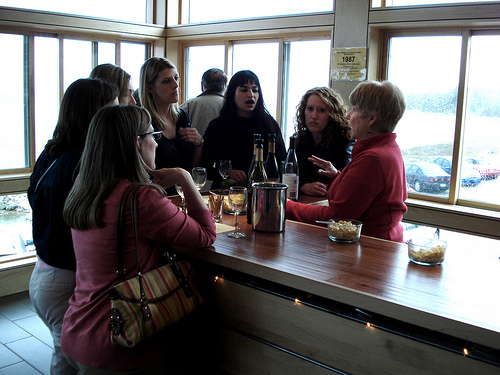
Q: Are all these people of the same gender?
A: Yes, all the people are female.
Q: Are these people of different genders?
A: No, all the people are female.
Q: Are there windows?
A: Yes, there is a window.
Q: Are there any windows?
A: Yes, there is a window.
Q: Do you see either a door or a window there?
A: Yes, there is a window.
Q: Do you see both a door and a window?
A: No, there is a window but no doors.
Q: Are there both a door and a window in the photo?
A: No, there is a window but no doors.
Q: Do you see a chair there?
A: No, there are no chairs.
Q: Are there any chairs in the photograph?
A: No, there are no chairs.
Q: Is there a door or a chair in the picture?
A: No, there are no chairs or doors.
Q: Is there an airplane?
A: No, there are no airplanes.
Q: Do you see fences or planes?
A: No, there are no planes or fences.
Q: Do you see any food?
A: Yes, there is food.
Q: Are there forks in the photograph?
A: No, there are no forks.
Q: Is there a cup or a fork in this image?
A: No, there are no forks or cups.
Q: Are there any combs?
A: No, there are no combs.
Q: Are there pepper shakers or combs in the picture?
A: No, there are no combs or pepper shakers.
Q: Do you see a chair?
A: No, there are no chairs.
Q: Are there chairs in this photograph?
A: No, there are no chairs.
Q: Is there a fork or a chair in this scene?
A: No, there are no chairs or forks.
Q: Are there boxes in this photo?
A: No, there are no boxes.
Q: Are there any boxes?
A: No, there are no boxes.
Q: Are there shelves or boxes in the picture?
A: No, there are no boxes or shelves.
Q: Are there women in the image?
A: Yes, there is a woman.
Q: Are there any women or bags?
A: Yes, there is a woman.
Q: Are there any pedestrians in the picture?
A: No, there are no pedestrians.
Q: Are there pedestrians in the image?
A: No, there are no pedestrians.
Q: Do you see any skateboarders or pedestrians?
A: No, there are no pedestrians or skateboarders.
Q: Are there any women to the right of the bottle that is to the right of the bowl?
A: Yes, there is a woman to the right of the bottle.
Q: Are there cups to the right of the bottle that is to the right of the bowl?
A: No, there is a woman to the right of the bottle.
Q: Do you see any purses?
A: Yes, there is a purse.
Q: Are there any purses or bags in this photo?
A: Yes, there is a purse.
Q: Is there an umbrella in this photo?
A: No, there are no umbrellas.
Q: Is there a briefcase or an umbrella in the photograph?
A: No, there are no umbrellas or briefcases.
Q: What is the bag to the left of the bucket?
A: The bag is a purse.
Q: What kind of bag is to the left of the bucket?
A: The bag is a purse.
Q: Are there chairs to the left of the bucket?
A: No, there is a purse to the left of the bucket.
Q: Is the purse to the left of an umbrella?
A: No, the purse is to the left of the bucket.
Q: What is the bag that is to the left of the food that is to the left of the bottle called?
A: The bag is a purse.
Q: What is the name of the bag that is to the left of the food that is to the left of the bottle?
A: The bag is a purse.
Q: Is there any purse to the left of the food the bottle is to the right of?
A: Yes, there is a purse to the left of the food.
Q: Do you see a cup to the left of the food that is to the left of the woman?
A: No, there is a purse to the left of the food.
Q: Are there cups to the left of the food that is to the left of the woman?
A: No, there is a purse to the left of the food.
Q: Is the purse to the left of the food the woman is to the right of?
A: Yes, the purse is to the left of the food.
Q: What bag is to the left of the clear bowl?
A: The bag is a purse.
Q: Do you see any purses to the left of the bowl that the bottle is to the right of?
A: Yes, there is a purse to the left of the bowl.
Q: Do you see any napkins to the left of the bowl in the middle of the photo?
A: No, there is a purse to the left of the bowl.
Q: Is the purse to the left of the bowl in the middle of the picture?
A: Yes, the purse is to the left of the bowl.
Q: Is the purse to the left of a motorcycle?
A: No, the purse is to the left of the bowl.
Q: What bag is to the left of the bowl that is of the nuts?
A: The bag is a purse.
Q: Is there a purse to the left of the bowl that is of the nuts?
A: Yes, there is a purse to the left of the bowl.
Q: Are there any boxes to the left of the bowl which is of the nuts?
A: No, there is a purse to the left of the bowl.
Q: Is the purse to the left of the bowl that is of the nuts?
A: Yes, the purse is to the left of the bowl.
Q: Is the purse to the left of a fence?
A: No, the purse is to the left of the bowl.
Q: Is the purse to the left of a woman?
A: No, the purse is to the right of a woman.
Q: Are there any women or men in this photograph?
A: Yes, there is a woman.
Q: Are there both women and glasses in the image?
A: Yes, there are both a woman and glasses.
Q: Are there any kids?
A: No, there are no kids.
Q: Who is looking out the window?
A: The woman is looking out the window.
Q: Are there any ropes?
A: No, there are no ropes.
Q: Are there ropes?
A: No, there are no ropes.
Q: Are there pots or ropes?
A: No, there are no ropes or pots.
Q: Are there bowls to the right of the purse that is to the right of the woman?
A: Yes, there is a bowl to the right of the purse.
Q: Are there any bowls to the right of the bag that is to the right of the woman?
A: Yes, there is a bowl to the right of the purse.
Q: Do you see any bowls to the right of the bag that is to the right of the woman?
A: Yes, there is a bowl to the right of the purse.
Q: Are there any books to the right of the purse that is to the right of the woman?
A: No, there is a bowl to the right of the purse.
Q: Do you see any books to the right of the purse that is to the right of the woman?
A: No, there is a bowl to the right of the purse.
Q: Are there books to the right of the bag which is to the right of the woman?
A: No, there is a bowl to the right of the purse.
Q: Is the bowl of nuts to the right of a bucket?
A: Yes, the bowl is to the right of a bucket.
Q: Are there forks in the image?
A: No, there are no forks.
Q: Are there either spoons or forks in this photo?
A: No, there are no forks or spoons.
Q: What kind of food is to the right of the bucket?
A: The food is nuts.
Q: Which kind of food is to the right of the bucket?
A: The food is nuts.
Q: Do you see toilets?
A: No, there are no toilets.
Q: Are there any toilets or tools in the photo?
A: No, there are no toilets or tools.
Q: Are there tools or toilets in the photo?
A: No, there are no toilets or tools.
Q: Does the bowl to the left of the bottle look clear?
A: Yes, the bowl is clear.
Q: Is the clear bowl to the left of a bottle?
A: Yes, the bowl is to the left of a bottle.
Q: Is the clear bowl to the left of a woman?
A: Yes, the bowl is to the left of a woman.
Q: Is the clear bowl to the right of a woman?
A: No, the bowl is to the left of a woman.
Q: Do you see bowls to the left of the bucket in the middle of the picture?
A: Yes, there is a bowl to the left of the bucket.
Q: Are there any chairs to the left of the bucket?
A: No, there is a bowl to the left of the bucket.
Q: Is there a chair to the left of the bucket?
A: No, there is a bowl to the left of the bucket.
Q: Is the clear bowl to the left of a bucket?
A: Yes, the bowl is to the left of a bucket.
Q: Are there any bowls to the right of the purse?
A: Yes, there is a bowl to the right of the purse.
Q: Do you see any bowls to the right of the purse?
A: Yes, there is a bowl to the right of the purse.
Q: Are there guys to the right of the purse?
A: No, there is a bowl to the right of the purse.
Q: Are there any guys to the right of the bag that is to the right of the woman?
A: No, there is a bowl to the right of the purse.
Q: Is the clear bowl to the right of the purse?
A: Yes, the bowl is to the right of the purse.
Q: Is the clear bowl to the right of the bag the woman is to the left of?
A: Yes, the bowl is to the right of the purse.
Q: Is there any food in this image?
A: Yes, there is food.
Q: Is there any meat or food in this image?
A: Yes, there is food.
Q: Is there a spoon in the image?
A: No, there are no spoons.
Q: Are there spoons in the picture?
A: No, there are no spoons.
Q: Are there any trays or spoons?
A: No, there are no spoons or trays.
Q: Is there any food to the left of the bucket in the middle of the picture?
A: Yes, there is food to the left of the bucket.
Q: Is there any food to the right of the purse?
A: Yes, there is food to the right of the purse.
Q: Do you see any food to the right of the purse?
A: Yes, there is food to the right of the purse.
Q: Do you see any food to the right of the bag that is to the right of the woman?
A: Yes, there is food to the right of the purse.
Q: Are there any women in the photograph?
A: Yes, there is a woman.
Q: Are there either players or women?
A: Yes, there is a woman.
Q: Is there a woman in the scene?
A: Yes, there is a woman.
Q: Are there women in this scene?
A: Yes, there is a woman.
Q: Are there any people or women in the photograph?
A: Yes, there is a woman.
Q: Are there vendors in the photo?
A: No, there are no vendors.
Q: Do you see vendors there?
A: No, there are no vendors.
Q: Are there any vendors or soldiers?
A: No, there are no vendors or soldiers.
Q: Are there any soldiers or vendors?
A: No, there are no vendors or soldiers.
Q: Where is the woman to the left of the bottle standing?
A: The woman is standing at the table.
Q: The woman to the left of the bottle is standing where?
A: The woman is standing at the table.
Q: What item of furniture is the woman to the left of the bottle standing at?
A: The woman is standing at the table.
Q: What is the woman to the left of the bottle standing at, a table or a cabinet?
A: The woman is standing at a table.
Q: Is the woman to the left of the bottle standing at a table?
A: Yes, the woman is standing at a table.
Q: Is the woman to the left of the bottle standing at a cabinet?
A: No, the woman is standing at a table.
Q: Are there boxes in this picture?
A: No, there are no boxes.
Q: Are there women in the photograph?
A: Yes, there is a woman.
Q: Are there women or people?
A: Yes, there is a woman.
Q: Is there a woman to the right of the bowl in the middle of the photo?
A: Yes, there is a woman to the right of the bowl.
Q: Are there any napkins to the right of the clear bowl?
A: No, there is a woman to the right of the bowl.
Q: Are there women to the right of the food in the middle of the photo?
A: Yes, there is a woman to the right of the food.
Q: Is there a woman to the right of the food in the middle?
A: Yes, there is a woman to the right of the food.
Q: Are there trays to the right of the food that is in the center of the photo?
A: No, there is a woman to the right of the food.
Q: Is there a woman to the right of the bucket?
A: Yes, there is a woman to the right of the bucket.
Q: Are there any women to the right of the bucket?
A: Yes, there is a woman to the right of the bucket.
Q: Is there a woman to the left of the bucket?
A: No, the woman is to the right of the bucket.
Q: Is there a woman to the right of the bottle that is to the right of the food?
A: Yes, there is a woman to the right of the bottle.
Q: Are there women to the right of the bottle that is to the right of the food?
A: Yes, there is a woman to the right of the bottle.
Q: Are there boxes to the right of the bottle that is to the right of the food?
A: No, there is a woman to the right of the bottle.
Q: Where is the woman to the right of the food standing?
A: The woman is standing at the table.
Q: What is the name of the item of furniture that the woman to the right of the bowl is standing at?
A: The piece of furniture is a table.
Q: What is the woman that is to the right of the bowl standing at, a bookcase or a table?
A: The woman is standing at a table.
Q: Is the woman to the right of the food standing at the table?
A: Yes, the woman is standing at the table.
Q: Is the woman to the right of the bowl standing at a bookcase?
A: No, the woman is standing at the table.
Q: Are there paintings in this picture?
A: No, there are no paintings.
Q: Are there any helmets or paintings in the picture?
A: No, there are no paintings or helmets.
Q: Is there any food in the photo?
A: Yes, there is food.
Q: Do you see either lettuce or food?
A: Yes, there is food.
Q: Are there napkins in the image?
A: No, there are no napkins.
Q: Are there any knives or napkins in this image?
A: No, there are no napkins or knives.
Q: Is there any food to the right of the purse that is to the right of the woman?
A: Yes, there is food to the right of the purse.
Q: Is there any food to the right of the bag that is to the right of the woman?
A: Yes, there is food to the right of the purse.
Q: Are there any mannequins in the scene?
A: No, there are no mannequins.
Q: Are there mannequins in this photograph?
A: No, there are no mannequins.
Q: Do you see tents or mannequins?
A: No, there are no mannequins or tents.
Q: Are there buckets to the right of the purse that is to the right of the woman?
A: Yes, there is a bucket to the right of the purse.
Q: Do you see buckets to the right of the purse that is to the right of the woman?
A: Yes, there is a bucket to the right of the purse.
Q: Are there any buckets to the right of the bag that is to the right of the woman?
A: Yes, there is a bucket to the right of the purse.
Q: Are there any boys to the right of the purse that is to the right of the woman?
A: No, there is a bucket to the right of the purse.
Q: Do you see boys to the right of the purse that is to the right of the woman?
A: No, there is a bucket to the right of the purse.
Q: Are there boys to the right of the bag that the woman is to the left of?
A: No, there is a bucket to the right of the purse.